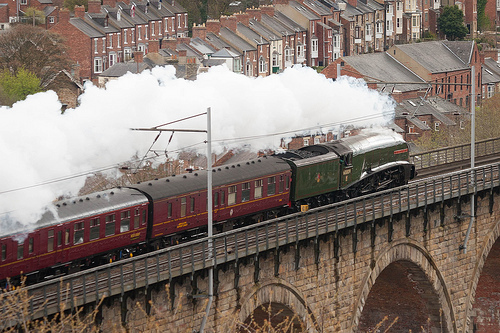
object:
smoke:
[0, 63, 396, 243]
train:
[0, 128, 418, 294]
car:
[271, 144, 341, 202]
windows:
[89, 216, 100, 241]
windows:
[120, 209, 131, 233]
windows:
[181, 197, 187, 217]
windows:
[254, 179, 264, 199]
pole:
[197, 107, 213, 332]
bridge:
[7, 190, 499, 332]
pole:
[462, 65, 491, 254]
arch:
[347, 235, 452, 329]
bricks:
[335, 285, 354, 296]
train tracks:
[216, 243, 225, 259]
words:
[179, 222, 187, 226]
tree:
[435, 4, 470, 40]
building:
[51, 11, 113, 80]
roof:
[67, 16, 106, 38]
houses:
[385, 40, 472, 109]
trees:
[0, 63, 49, 108]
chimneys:
[206, 19, 220, 35]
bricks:
[213, 24, 217, 30]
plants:
[383, 316, 399, 332]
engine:
[314, 126, 419, 201]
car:
[124, 155, 293, 238]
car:
[5, 192, 149, 286]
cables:
[179, 100, 470, 130]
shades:
[181, 197, 187, 218]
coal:
[287, 149, 329, 158]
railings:
[245, 226, 249, 256]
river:
[356, 259, 449, 333]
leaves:
[28, 71, 31, 75]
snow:
[340, 127, 407, 158]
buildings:
[324, 34, 499, 123]